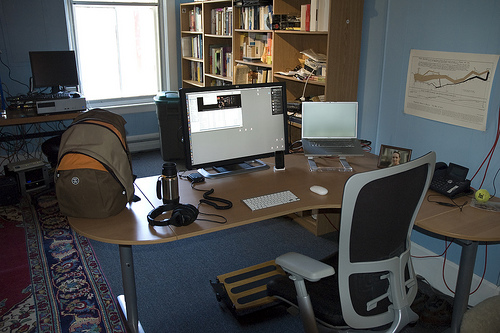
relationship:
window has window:
[71, 4, 163, 100] [71, 4, 163, 100]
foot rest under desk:
[213, 263, 302, 318] [79, 133, 496, 329]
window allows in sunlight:
[71, 4, 163, 100] [73, 3, 164, 94]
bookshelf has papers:
[269, 2, 331, 118] [283, 39, 330, 78]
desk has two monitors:
[79, 133, 496, 329] [180, 83, 365, 165]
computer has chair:
[180, 83, 365, 165] [273, 159, 431, 333]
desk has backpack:
[79, 133, 496, 329] [51, 110, 133, 222]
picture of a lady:
[375, 142, 409, 168] [388, 150, 403, 165]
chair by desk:
[273, 159, 431, 333] [79, 133, 496, 329]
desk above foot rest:
[79, 133, 496, 329] [213, 263, 302, 318]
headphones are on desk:
[148, 196, 203, 228] [79, 133, 496, 329]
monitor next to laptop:
[177, 84, 288, 165] [302, 102, 366, 162]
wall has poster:
[382, 2, 498, 182] [400, 36, 499, 136]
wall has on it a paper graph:
[382, 2, 498, 182] [400, 36, 499, 136]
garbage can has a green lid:
[151, 89, 194, 163] [153, 88, 185, 107]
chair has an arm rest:
[273, 159, 431, 333] [271, 249, 334, 285]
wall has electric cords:
[382, 2, 498, 182] [473, 107, 500, 188]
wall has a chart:
[382, 2, 498, 182] [400, 36, 499, 136]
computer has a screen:
[185, 86, 306, 209] [177, 84, 288, 165]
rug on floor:
[5, 209, 75, 331] [11, 196, 273, 327]